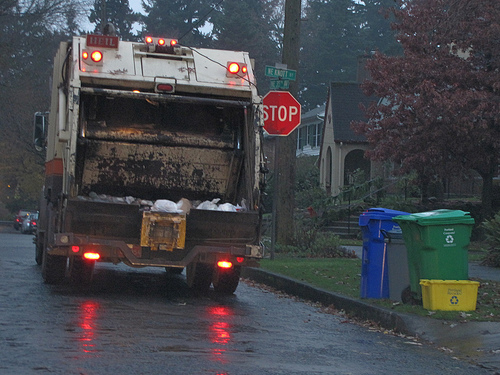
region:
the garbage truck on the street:
[42, 20, 279, 298]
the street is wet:
[0, 290, 376, 372]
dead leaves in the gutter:
[250, 281, 407, 358]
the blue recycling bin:
[356, 196, 408, 308]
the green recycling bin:
[390, 203, 480, 268]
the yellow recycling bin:
[410, 273, 485, 312]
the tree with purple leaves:
[350, 6, 492, 184]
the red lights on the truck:
[72, 39, 260, 87]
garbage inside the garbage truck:
[92, 183, 246, 215]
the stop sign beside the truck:
[252, 80, 297, 137]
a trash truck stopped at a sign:
[17, 24, 340, 316]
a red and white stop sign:
[258, 90, 303, 142]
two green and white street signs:
[258, 64, 299, 89]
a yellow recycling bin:
[417, 275, 482, 312]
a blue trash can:
[354, 204, 395, 305]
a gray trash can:
[379, 220, 416, 305]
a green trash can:
[392, 208, 475, 280]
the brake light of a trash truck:
[81, 245, 103, 263]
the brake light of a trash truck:
[213, 258, 234, 269]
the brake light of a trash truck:
[91, 49, 101, 63]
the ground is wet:
[6, 275, 432, 373]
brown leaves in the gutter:
[250, 276, 413, 354]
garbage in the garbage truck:
[87, 172, 248, 214]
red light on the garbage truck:
[65, 248, 105, 265]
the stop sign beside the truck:
[259, 79, 302, 247]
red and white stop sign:
[258, 88, 303, 138]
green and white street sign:
[261, 61, 298, 83]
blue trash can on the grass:
[356, 204, 409, 299]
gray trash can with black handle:
[378, 223, 415, 302]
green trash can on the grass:
[391, 206, 474, 301]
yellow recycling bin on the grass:
[418, 276, 483, 313]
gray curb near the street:
[246, 263, 411, 334]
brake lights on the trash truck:
[66, 242, 249, 272]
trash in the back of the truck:
[78, 188, 247, 215]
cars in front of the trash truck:
[11, 204, 42, 233]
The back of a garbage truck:
[72, 26, 262, 301]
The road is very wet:
[1, 229, 496, 373]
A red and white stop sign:
[393, 205, 477, 294]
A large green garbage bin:
[393, 205, 478, 299]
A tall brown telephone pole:
[268, 5, 304, 247]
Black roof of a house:
[326, 77, 384, 145]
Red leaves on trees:
[345, 6, 496, 184]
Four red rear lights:
[66, 237, 246, 274]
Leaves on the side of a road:
[237, 270, 424, 350]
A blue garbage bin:
[355, 202, 413, 303]